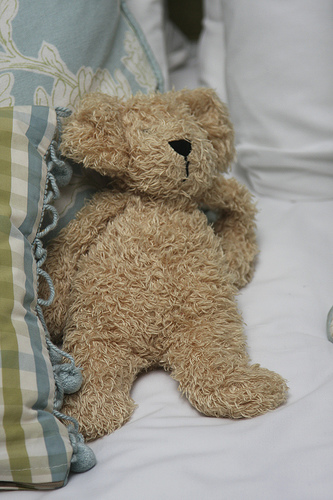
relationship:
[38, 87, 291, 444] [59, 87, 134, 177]
teddy bear has ear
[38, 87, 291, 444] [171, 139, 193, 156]
teddy bear has nose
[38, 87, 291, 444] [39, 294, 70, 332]
teddy bear has paw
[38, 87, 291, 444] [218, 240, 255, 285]
teddy bear has paw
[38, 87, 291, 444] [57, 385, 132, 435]
teddy bear has paw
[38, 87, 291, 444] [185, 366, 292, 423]
teddy bear has paw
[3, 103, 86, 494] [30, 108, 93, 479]
pillow has fringe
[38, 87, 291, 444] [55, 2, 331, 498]
teddy bear on top of sheet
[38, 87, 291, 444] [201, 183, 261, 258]
teddy bear has arm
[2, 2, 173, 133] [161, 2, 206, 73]
coverlet next to shadow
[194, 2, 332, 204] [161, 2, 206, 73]
pillow next to shadow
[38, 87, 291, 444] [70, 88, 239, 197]
teddy bear has head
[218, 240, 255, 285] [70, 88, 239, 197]
paw leaning on head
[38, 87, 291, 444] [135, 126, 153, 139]
teddy bear has eye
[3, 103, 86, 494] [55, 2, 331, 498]
pillow on top of sheet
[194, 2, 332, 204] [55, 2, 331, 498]
pillow on top of sheet